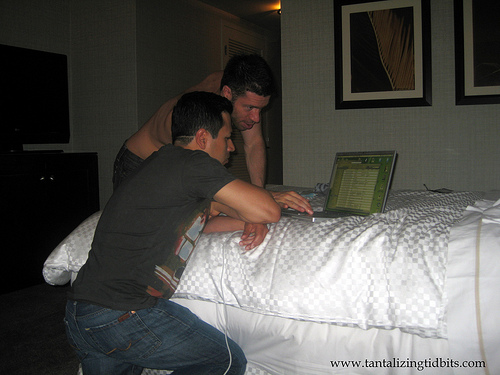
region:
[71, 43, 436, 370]
There is a laptop in the photo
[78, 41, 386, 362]
There are two males in the photo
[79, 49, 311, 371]
There are two people in the photo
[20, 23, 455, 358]
The photo is taken in a bedroom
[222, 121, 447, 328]
The laptop is on the bed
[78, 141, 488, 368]
The bed spread is white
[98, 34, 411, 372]
The two males are looking at a laptop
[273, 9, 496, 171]
There are pictures hanging on a wall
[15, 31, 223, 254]
There is a tv in the background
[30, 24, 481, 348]
The picture was taken inside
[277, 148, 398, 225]
Working laptop computer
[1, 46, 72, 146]
Unused flat screen television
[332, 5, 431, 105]
Abstract wall art in dark frame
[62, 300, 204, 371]
Medium wash blue jeans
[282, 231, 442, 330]
White checkered duvet cover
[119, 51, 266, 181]
Shirtless man bending over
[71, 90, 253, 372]
Man kneeling on the floor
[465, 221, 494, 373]
Off white trim on white sheets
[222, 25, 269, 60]
Top of vented door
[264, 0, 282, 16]
Hall light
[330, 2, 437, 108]
photograph in a frame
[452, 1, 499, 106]
picture hanging on a wall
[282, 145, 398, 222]
the computer is on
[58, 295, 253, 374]
the jeans are blue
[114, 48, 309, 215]
the man is shirtless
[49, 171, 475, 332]
the bed spread is white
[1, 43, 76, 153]
the television is turned off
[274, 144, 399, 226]
the computer is on the bed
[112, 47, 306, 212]
the man is standing over the bed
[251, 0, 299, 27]
the light in the hall is turned on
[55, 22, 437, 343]
Two men looking at a laptop.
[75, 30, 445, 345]
Two men viewing a laptop.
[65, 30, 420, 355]
Two men interested with a laptop.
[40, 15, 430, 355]
Some young men looking at a laptop.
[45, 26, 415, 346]
Some young men busy with a laptop.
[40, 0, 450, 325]
Some young men interested in a laptop.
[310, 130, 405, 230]
laptop on a bed.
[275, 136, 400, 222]
hand working a laptop.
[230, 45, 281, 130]
person with dark colored hair.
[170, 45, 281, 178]
two people with dark hair.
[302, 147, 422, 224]
Laptop logged into what looks like Windows.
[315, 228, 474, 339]
White comforter on bed.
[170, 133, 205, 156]
Poor fade haircut on guy leaning on bed.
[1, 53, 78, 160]
TV on dresser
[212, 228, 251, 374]
Power cord or mouse cord hanging off bed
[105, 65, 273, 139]
Male individual not wearing a t-shirt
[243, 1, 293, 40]
Ceiling light turned on.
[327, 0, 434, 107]
Picture on wall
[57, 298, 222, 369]
Jeans worn by male individual leaning on bed.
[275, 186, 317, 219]
Hand using touchpad on laptop to control laptop.